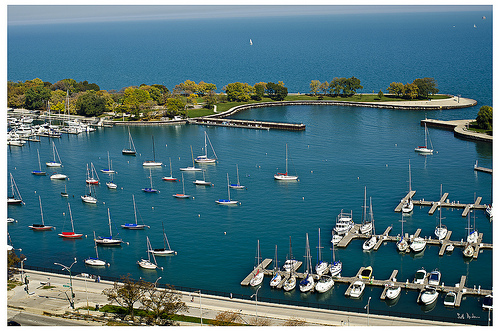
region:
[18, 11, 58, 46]
white clouds in blue sky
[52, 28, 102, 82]
white clouds in blue sky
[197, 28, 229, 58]
white clouds in blue sky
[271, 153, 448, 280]
boats in harbor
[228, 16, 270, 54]
white clouds in blue sky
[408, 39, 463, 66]
white clouds in blue sky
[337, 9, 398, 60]
white clouds in blue sky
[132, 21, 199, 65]
white clouds in blue sky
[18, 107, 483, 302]
yachts and boats in the water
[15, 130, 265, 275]
boats have masts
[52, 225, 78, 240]
a red boat with a mast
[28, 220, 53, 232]
a red boat with a mast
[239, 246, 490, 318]
boats are parked on a dock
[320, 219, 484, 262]
boats are parked on a dock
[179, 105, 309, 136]
a dock on left side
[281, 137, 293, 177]
a mast of a boat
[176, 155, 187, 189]
a mast of a boat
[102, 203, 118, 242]
a mast of a boat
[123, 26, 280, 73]
water is dark blue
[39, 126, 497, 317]
many boats in harbor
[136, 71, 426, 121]
green trees near water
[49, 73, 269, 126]
green and yellow trees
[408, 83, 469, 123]
light brown beach near water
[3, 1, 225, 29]
sky is blue and hazy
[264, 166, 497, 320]
white boats in docks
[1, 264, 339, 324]
grey road near water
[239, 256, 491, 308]
grey docks near water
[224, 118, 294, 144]
pier jutting into water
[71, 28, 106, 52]
white clouds in blue sky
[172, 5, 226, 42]
white clouds in blue sky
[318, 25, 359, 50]
white clouds in blue sky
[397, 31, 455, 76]
white clouds in blue sky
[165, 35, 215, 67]
white clouds in blue sky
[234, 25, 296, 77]
white clouds in blue sky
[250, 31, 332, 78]
white clouds in blue sky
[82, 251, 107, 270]
THAT IS A BOAT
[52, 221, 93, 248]
THAT IS A BOAT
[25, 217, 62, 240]
THAT IS A BOAT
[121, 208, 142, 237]
THAT IS A BOAT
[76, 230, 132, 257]
THAT IS A BOAT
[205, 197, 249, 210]
THAT IS A BOAT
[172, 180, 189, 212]
THAT IS A BOAT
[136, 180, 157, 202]
THAT IS A BOAT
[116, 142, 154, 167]
THAT IS A BOAT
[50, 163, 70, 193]
THAT IS A BOAT